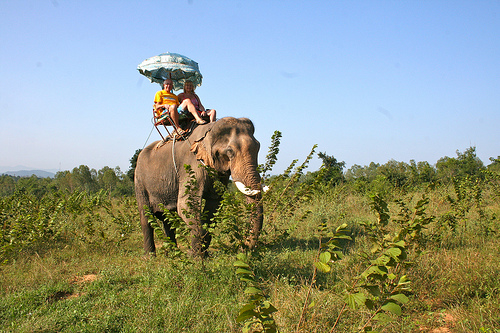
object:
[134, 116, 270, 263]
elephant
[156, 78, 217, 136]
couple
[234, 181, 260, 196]
tusk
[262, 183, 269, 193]
tusk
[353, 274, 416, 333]
plant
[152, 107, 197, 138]
saddle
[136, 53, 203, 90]
umbrella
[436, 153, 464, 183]
tree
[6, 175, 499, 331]
field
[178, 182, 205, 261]
leg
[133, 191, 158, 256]
leg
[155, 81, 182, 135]
man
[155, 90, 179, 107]
shirt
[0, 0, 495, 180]
sky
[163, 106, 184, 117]
shorts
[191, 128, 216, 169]
ear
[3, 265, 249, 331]
grass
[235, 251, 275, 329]
weed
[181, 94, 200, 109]
shirt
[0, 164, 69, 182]
mountains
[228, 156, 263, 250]
trunk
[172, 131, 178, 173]
strap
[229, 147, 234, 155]
eye